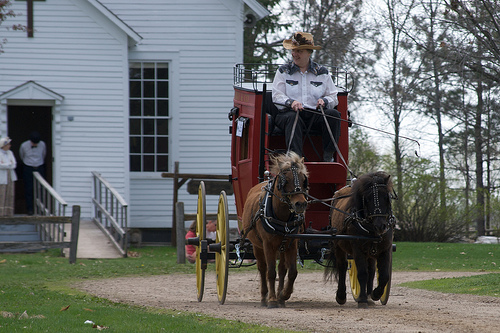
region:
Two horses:
[229, 143, 407, 310]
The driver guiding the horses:
[250, 20, 390, 270]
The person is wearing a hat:
[272, 22, 339, 109]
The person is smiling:
[273, 23, 328, 80]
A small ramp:
[44, 162, 124, 258]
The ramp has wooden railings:
[25, 164, 137, 266]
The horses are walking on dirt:
[235, 143, 398, 324]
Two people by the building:
[0, 123, 57, 210]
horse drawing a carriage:
[240, 145, 321, 321]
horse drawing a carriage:
[322, 156, 439, 301]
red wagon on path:
[211, 71, 380, 220]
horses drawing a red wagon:
[198, 45, 458, 327]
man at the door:
[21, 124, 63, 173]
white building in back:
[6, 0, 258, 262]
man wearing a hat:
[278, 15, 317, 53]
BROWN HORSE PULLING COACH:
[239, 149, 307, 309]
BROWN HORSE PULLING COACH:
[321, 166, 401, 305]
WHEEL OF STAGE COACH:
[213, 191, 235, 310]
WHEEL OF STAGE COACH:
[188, 175, 213, 307]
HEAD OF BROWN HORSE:
[265, 146, 316, 226]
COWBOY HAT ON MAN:
[280, 28, 322, 52]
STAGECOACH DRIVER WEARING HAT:
[271, 26, 345, 163]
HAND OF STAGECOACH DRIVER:
[283, 95, 307, 117]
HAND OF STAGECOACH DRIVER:
[311, 93, 331, 113]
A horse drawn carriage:
[185, 29, 397, 309]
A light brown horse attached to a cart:
[244, 149, 310, 304]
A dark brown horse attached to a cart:
[330, 170, 400, 309]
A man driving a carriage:
[271, 33, 341, 166]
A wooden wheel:
[207, 191, 237, 301]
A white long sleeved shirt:
[269, 60, 339, 112]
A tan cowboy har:
[282, 31, 323, 51]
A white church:
[1, 0, 274, 259]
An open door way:
[8, 104, 53, 214]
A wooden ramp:
[32, 169, 132, 259]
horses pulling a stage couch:
[176, 27, 403, 302]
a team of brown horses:
[230, 150, 400, 295]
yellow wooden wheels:
[190, 181, 230, 296]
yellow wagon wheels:
[187, 180, 229, 296]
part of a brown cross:
[0, 0, 50, 36]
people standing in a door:
[0, 121, 51, 213]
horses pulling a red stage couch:
[193, 67, 400, 309]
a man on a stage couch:
[273, 37, 340, 159]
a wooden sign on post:
[174, 159, 235, 206]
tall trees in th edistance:
[412, 13, 497, 243]